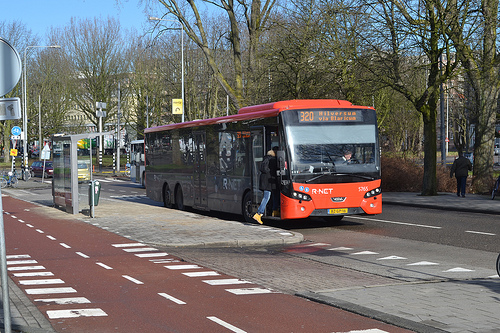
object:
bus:
[145, 100, 383, 225]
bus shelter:
[51, 132, 114, 219]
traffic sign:
[171, 98, 183, 114]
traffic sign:
[10, 125, 22, 135]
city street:
[0, 166, 499, 332]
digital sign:
[299, 111, 357, 121]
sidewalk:
[381, 190, 500, 214]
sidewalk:
[0, 274, 54, 333]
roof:
[143, 97, 375, 133]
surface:
[0, 195, 419, 332]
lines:
[343, 214, 440, 233]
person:
[252, 150, 281, 225]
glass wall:
[73, 138, 93, 217]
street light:
[147, 16, 161, 22]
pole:
[159, 18, 185, 123]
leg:
[258, 189, 271, 215]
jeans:
[257, 190, 272, 215]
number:
[299, 111, 314, 121]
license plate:
[325, 207, 350, 215]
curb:
[76, 192, 304, 248]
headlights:
[291, 190, 296, 199]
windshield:
[284, 125, 381, 183]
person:
[450, 153, 471, 197]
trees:
[392, 1, 460, 203]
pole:
[22, 45, 50, 171]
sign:
[9, 148, 18, 156]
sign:
[40, 143, 50, 161]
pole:
[116, 81, 120, 174]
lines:
[2, 178, 499, 332]